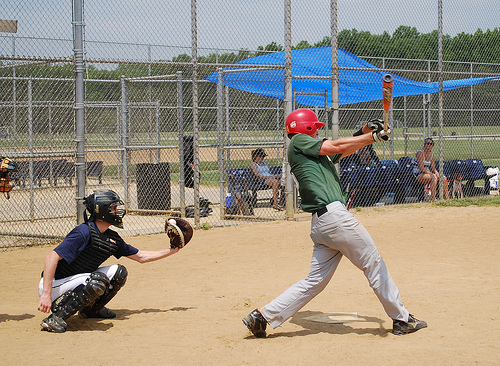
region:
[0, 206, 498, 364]
a baseball field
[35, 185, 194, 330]
the hind catcher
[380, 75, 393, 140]
a short bat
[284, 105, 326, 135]
red helmet on man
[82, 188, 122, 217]
a black helmet on head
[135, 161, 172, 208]
a black trash can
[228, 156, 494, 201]
the guest seats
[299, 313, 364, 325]
a home plate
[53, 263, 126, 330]
the shin guards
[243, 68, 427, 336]
a man batting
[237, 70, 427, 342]
Baseball player swinging a bat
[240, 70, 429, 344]
Baseball wearing a green jersey swinging a bat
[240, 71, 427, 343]
Baseball player with a red helmet on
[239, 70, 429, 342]
Baseball player with a red helmet on swinging a bat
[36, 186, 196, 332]
Umpire in white pants catching a baseball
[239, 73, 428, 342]
Baseball player wearing white pants swinging his bat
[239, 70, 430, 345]
Baseball player wearing a red helmet and white pants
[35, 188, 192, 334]
Umpire wearing a blue jersey and white pants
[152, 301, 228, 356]
The dirt on the ground is brown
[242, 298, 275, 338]
The shoe of the man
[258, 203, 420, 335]
The man is wearing pants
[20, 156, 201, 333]
The catcher is on the ground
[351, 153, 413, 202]
The seats outside the gate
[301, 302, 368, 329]
The baseball plate on the ground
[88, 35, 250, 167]
The gate is made of metal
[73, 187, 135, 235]
The man is wearing a helmet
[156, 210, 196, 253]
The man has on a baseball glove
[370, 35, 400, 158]
The man is holding the bat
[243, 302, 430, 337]
Man wearing shoes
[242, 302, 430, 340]
Man is wearing shoes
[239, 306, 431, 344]
Man wearing black and white shoes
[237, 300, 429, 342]
Man is wearing black and white shoes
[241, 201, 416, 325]
Man wearing pants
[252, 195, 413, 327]
Man is wearing pants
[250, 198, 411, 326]
Man wearing white pants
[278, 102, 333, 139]
Man wearing a red helmet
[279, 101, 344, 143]
Man is wearing a red baseball helmet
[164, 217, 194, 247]
A baseball mitt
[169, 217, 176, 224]
A baseball in the mitt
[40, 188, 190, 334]
The catcher behind the hitter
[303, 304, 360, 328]
Home base on the ground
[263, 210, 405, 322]
A pair of tan pants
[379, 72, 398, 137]
A baseball bat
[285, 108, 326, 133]
A red baseball helmet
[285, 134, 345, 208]
A green shirt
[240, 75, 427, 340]
A baseball playing swinging a bat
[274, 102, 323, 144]
the helmet of a man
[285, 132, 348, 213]
the shirt of a man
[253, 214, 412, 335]
the pants of a man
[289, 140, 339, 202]
the body of a man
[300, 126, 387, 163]
the arms of a man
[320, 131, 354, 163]
the elbow of a man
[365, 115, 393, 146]
the hands of a man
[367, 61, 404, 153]
the bat of a man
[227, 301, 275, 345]
the left shoe of a man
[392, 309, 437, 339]
the right shoe of a man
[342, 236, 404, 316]
person has a leg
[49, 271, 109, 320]
person has a leg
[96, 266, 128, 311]
person has a leg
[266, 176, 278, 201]
person has a leg